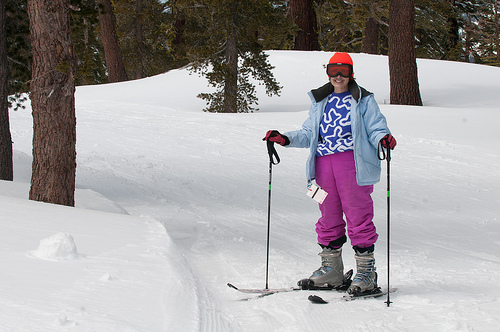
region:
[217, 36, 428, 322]
Girl outside in ski outfit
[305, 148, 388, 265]
Purple ski pants on skier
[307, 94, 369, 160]
Blue and white ski shirt on skier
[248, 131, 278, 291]
Black pole for sking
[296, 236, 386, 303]
Two grey ski shoes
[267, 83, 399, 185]
Light blue and black ski jacket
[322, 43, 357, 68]
Orange ski cap on girl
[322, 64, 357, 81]
Black and red ski goggles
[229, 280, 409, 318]
Black and grey skis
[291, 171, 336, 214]
Black and white tag on skier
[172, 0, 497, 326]
woman standing in snow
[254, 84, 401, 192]
woman wearing blue jacket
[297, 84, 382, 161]
man wearing blue and white shirt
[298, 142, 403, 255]
woman wearing purple pants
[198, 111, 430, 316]
holding a pair of ski poles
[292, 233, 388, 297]
woman wearing grey pants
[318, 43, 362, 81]
woman wearing orange hat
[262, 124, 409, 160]
woman wearing red gloves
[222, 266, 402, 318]
black bottom of skis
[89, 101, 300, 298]
ski tracks in snow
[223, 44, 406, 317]
A woman is skiing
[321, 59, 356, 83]
A pair of goggles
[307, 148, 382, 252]
The pants are bright pink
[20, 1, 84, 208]
A brown tree trunk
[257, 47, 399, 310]
Skiier is holding ski poles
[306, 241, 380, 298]
A pair of ski boots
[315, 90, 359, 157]
A blue and white sweater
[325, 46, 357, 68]
The hat is bright orange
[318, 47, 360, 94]
The woman is smiling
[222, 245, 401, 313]
Two skis under two boots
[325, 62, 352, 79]
big black snow goggles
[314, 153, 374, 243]
dark pink snow pants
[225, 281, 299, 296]
long white snow ski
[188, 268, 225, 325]
tire tracks in powdery snow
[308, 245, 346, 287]
tall grey snow boots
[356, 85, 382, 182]
light blue ski jacket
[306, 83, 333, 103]
light blue and black collar of ski jacket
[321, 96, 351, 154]
dark blue sweater with white designs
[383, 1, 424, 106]
brown tree in snow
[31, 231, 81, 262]
pile of white snow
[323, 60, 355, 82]
A pair of snow sport goggles.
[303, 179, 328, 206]
A ski slope pass attached to a zipper pull.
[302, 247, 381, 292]
A pair of ski boots.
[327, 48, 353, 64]
A bright orange hat.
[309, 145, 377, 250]
A pair of purple pants.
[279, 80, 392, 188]
A light blue winter coat.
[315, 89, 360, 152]
A blue shirt with white lines.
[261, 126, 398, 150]
A pair of winter gloves being worn.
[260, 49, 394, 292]
A woman skiing in the woods.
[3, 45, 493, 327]
A very large area of white snow.